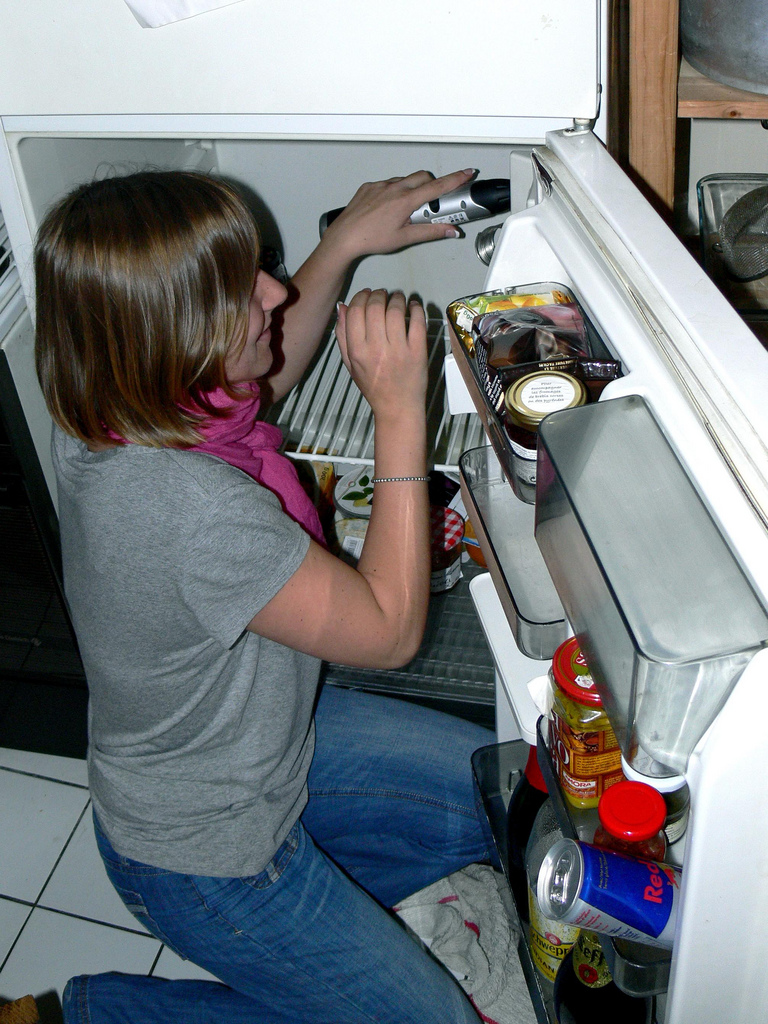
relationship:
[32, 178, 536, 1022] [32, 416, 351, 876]
woman wearing shirt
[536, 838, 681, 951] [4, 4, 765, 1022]
bottle inside fridge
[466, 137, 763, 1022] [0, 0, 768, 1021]
door attached to fridge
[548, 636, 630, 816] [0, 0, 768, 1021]
bottle in fridge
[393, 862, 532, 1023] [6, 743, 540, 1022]
towel on ground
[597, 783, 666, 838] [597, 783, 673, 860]
lid on bottle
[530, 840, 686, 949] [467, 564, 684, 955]
bottle on shelf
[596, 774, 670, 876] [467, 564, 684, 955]
bottle on shelf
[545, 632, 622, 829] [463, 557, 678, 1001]
bottle on shelf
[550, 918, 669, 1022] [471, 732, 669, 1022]
bottle on shelf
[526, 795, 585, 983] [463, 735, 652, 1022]
bottle on shelf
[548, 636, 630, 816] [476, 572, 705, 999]
bottle on shelf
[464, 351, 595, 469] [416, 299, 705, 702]
bottle on shelf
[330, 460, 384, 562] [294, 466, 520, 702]
bottle on shelf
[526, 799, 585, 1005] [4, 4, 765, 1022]
bottle in fridge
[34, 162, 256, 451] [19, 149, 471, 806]
hair on head of woman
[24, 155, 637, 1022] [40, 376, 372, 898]
woman wearing shirt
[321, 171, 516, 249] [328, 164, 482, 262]
screwdriver in hand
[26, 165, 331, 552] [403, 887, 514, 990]
woman on towel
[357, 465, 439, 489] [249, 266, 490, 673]
bracelet on arm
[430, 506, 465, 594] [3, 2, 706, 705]
food in fridge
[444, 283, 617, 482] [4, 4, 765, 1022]
food in fridge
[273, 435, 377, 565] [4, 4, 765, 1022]
food in fridge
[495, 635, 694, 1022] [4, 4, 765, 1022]
food in fridge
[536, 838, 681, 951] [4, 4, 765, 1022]
bottle in fridge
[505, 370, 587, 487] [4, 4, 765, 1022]
bottle in fridge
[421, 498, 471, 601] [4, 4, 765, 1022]
food in fridge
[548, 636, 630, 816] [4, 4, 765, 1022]
bottle in fridge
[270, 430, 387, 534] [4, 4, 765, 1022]
food in fridge